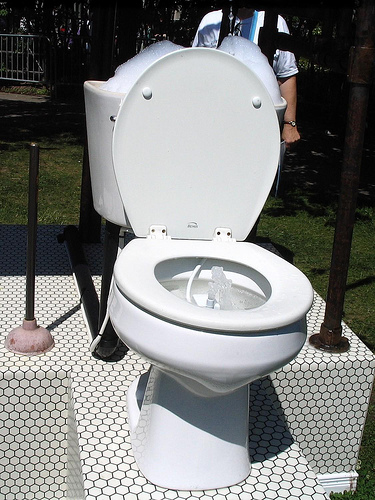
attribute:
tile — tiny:
[22, 398, 38, 415]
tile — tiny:
[32, 447, 45, 457]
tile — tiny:
[98, 469, 115, 481]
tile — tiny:
[266, 436, 283, 447]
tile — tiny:
[289, 404, 303, 416]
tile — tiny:
[316, 380, 330, 394]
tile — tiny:
[328, 368, 340, 378]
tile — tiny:
[58, 304, 69, 312]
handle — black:
[21, 139, 40, 323]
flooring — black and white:
[2, 269, 372, 498]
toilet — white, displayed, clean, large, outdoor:
[78, 45, 315, 492]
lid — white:
[105, 42, 281, 245]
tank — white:
[83, 78, 289, 232]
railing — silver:
[0, 30, 51, 84]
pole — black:
[309, 14, 373, 353]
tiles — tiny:
[28, 374, 39, 388]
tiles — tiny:
[32, 402, 45, 412]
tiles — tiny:
[103, 461, 116, 475]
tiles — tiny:
[267, 435, 281, 450]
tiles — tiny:
[331, 389, 338, 401]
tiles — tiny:
[82, 375, 94, 383]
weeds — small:
[326, 473, 369, 498]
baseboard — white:
[316, 469, 362, 498]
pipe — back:
[62, 222, 126, 363]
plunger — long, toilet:
[3, 314, 56, 355]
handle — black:
[16, 139, 40, 323]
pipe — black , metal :
[311, 3, 373, 353]